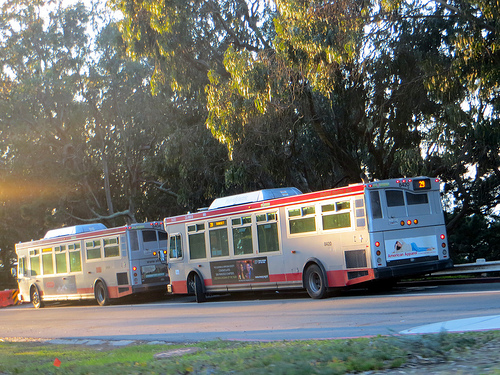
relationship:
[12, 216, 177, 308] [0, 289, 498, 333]
bus on road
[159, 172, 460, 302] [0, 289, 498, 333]
bus on road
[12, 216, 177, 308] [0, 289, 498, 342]
bus on road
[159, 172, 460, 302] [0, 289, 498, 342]
bus on road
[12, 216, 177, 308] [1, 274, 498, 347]
bus on road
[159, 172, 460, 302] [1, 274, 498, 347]
bus on road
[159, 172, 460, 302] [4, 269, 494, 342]
bus on street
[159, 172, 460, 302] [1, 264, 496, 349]
bus on road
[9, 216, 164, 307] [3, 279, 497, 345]
bus on street